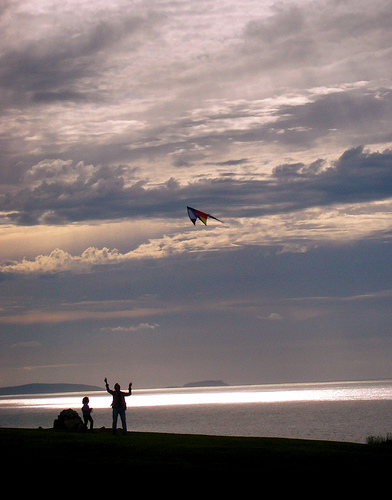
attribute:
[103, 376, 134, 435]
person — silhouetted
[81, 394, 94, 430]
person — silhouetted, young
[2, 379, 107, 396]
land — in distance, in background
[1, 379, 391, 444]
ocean water — still, large, calm, white capped, steady, sunlit shining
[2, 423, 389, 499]
hill — grassy, green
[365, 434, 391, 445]
patch of grass — small, tall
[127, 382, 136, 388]
hand — in air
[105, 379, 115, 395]
arm — in air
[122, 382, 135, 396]
arm — up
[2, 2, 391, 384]
clouds — backlit, light grey, suggesting storm, covering sun, reflecting sun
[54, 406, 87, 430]
vegetation — waterside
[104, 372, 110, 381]
handle — stringed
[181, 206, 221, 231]
kite — colorful, multi-colored, up in the air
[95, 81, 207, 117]
sky — cloudy, cloud covered, white, grey